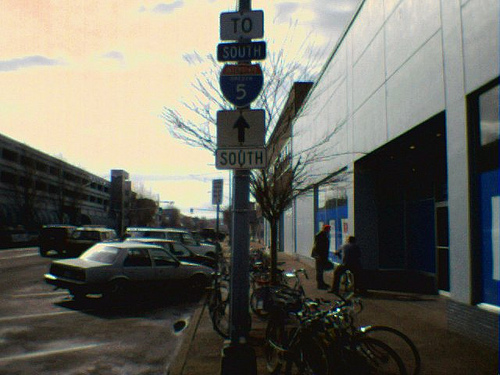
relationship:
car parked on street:
[50, 202, 210, 322] [51, 294, 141, 359]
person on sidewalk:
[305, 214, 343, 292] [366, 282, 438, 342]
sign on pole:
[216, 108, 266, 150] [222, 169, 257, 374]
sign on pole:
[214, 144, 273, 168] [195, 8, 292, 373]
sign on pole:
[213, 67, 263, 106] [219, 167, 258, 337]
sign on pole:
[215, 42, 270, 61] [218, 177, 263, 337]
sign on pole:
[215, 7, 264, 39] [228, 1, 257, 345]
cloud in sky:
[3, 11, 327, 214] [5, 1, 356, 221]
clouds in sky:
[88, 61, 208, 131] [5, 1, 356, 221]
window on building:
[315, 172, 347, 213] [257, 2, 489, 314]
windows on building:
[2, 142, 149, 228] [0, 135, 138, 250]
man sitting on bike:
[328, 235, 369, 296] [341, 266, 360, 288]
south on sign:
[211, 149, 271, 168] [212, 145, 269, 170]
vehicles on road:
[32, 203, 112, 253] [0, 225, 169, 302]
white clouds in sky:
[16, 10, 217, 172] [5, 1, 356, 221]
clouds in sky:
[1, 46, 123, 76] [5, 1, 356, 221]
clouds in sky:
[95, 132, 152, 169] [5, 1, 356, 221]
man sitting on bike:
[331, 231, 364, 288] [339, 266, 361, 296]